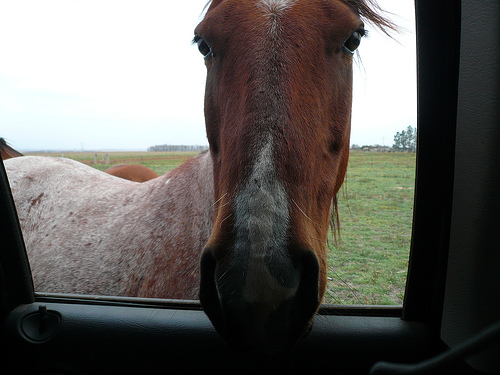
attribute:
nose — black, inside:
[199, 244, 320, 349]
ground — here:
[343, 143, 401, 236]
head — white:
[216, 16, 326, 265]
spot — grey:
[225, 151, 298, 244]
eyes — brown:
[183, 18, 384, 51]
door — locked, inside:
[27, 280, 320, 349]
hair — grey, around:
[158, 132, 336, 238]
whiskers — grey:
[257, 201, 338, 260]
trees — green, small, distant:
[353, 90, 433, 154]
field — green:
[81, 139, 220, 174]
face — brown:
[212, 52, 325, 263]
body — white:
[35, 162, 211, 307]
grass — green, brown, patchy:
[339, 145, 405, 356]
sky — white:
[34, 23, 155, 111]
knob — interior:
[376, 339, 443, 372]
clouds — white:
[14, 30, 222, 152]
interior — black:
[23, 218, 489, 366]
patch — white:
[139, 161, 282, 275]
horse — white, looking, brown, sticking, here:
[13, 0, 371, 335]